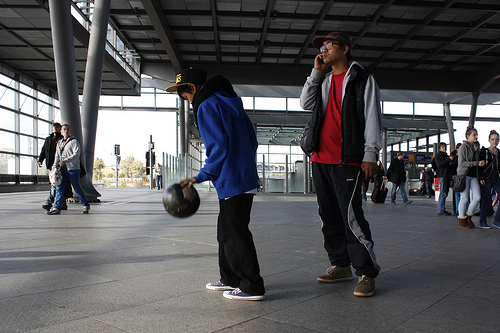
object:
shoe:
[316, 265, 355, 283]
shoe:
[352, 271, 375, 297]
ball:
[162, 182, 201, 219]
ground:
[386, 204, 406, 226]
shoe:
[205, 280, 239, 290]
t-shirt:
[308, 73, 345, 163]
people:
[36, 122, 91, 215]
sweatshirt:
[298, 62, 389, 166]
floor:
[2, 191, 499, 333]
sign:
[114, 144, 121, 155]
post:
[116, 155, 119, 188]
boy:
[161, 67, 266, 301]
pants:
[214, 181, 266, 296]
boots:
[458, 212, 476, 229]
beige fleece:
[457, 212, 474, 219]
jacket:
[192, 92, 259, 200]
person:
[384, 151, 413, 206]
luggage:
[370, 178, 390, 204]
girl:
[478, 130, 500, 230]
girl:
[450, 125, 486, 229]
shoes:
[222, 286, 265, 301]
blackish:
[162, 182, 202, 219]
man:
[37, 122, 72, 211]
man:
[44, 123, 93, 216]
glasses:
[320, 41, 345, 53]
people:
[386, 123, 498, 229]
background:
[119, 0, 499, 238]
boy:
[162, 61, 269, 302]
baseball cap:
[165, 66, 206, 92]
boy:
[297, 31, 384, 298]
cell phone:
[320, 56, 328, 65]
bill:
[165, 84, 180, 92]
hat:
[312, 32, 353, 54]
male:
[299, 31, 382, 296]